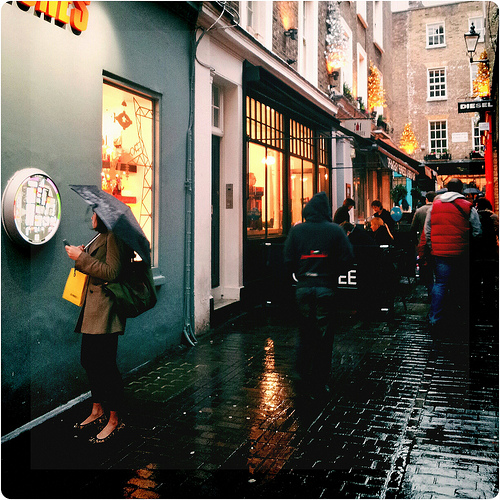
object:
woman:
[62, 207, 132, 445]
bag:
[60, 268, 87, 306]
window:
[440, 137, 447, 149]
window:
[439, 89, 445, 96]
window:
[426, 35, 433, 46]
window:
[473, 18, 483, 30]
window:
[473, 129, 476, 136]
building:
[391, 0, 498, 167]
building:
[193, 1, 437, 345]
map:
[12, 171, 63, 245]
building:
[0, 0, 202, 440]